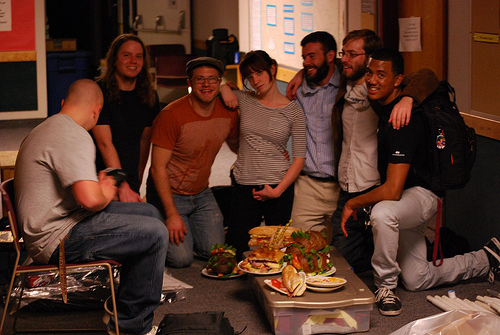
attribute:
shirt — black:
[88, 69, 157, 154]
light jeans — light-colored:
[373, 183, 490, 297]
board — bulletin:
[5, 0, 51, 111]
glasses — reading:
[184, 67, 226, 92]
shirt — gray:
[148, 87, 238, 193]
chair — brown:
[1, 175, 118, 333]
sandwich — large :
[245, 245, 285, 270]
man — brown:
[145, 52, 293, 269]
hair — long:
[93, 30, 161, 102]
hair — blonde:
[148, 68, 151, 88]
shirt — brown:
[191, 124, 204, 152]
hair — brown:
[245, 59, 267, 68]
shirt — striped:
[218, 49, 307, 255]